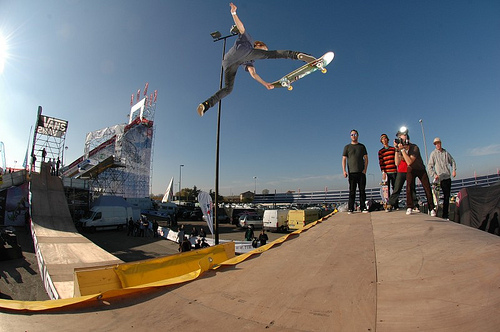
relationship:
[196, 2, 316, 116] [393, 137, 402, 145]
man holding camera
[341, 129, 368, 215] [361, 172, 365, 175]
boy has hand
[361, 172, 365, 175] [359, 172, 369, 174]
hand on pocket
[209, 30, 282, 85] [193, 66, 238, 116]
man has leg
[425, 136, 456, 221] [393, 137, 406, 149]
guy holding camera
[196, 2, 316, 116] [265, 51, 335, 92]
man holding skateboard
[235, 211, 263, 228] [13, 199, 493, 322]
car parked behind ramp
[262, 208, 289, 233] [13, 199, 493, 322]
van parked behind ramp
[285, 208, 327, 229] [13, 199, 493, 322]
cars parked behind ramp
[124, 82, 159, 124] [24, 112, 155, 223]
flags at top of ramp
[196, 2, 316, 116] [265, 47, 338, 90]
man holding skateboard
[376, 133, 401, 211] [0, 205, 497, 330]
boy standing on skateboard landing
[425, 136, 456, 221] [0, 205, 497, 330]
guy standing on skateboard landing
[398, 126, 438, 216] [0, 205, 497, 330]
boy standing on skateboard landing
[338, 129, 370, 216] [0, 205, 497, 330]
boy standing on skateboard landing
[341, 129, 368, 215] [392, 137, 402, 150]
boy holding camera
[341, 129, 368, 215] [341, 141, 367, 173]
boy wearing shirt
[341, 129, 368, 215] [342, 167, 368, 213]
boy wearing pants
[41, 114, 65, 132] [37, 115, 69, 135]
"vans" written on sign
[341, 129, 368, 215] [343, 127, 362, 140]
boy wearing sunglasses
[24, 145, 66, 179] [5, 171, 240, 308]
people standing on side ramp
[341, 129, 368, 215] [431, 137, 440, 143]
boy wearing ballcap